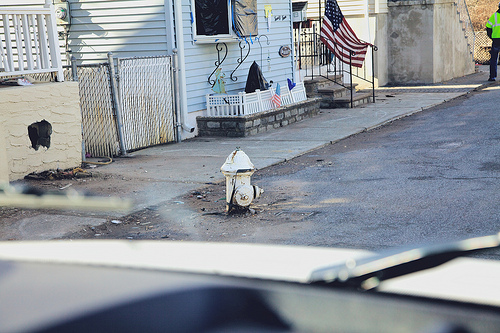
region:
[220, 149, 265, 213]
A white fire hydrant.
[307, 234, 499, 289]
A very close up windshield wiper.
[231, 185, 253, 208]
Large round white cap on a fire hydrant.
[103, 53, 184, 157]
A metal chain link gate.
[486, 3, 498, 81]
A person standing in dark jeans and a green vest.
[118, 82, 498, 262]
A grey concrete road.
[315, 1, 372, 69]
A red, white and blue larger American flag.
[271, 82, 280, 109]
A smaller red, white and blue American flag in front of a house.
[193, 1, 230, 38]
A black trashbag covering a window.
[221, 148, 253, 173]
The very top dome of a white hydrant.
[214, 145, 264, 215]
An old fire hydrant on a city street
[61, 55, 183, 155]
An old white gate between two buildings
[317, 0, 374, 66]
American flag hanging on a front porch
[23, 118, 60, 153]
Hole in a cement wall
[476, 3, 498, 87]
A construction worker on a city street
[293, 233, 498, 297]
A windshield wiper in a car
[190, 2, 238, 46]
Open window on an old house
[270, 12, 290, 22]
Metal address numbers on a house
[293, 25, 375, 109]
Metal porch railing by a front door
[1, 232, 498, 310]
The hood of a car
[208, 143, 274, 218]
Hydrant in the ground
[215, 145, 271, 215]
Hydrant is in the ground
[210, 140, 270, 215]
Fire hydrant in the ground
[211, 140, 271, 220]
Fire hydrant is in the ground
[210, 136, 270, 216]
White hydrant is in the ground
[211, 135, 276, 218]
White fire hydrant in the ground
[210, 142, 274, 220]
White fire hydrant is in the ground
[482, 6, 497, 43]
Man wearing a green reflective vest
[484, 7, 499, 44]
Man is wearing a green reflective vest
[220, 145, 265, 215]
short white fire hydrant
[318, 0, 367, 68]
American flag on porch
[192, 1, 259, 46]
black plastic taped around windows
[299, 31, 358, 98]
wrought iron railing on stairs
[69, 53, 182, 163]
white and grey chain link fence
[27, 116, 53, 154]
hole in concrete wall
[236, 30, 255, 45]
blue tape holding plastic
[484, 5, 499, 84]
man in green safety vest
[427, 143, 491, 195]
cracks in pavement on road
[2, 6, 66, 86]
white railing around porch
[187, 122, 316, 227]
a white fire hyrant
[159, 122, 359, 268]
a fire hydrant in the road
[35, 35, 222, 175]
a silver metal fence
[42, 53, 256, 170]
a metal fence along a building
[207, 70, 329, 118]
a white fence along a building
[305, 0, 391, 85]
the american flag on a building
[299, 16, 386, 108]
black railings on a staircase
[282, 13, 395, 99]
a staircase in front of a building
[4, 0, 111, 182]
a white railing on a building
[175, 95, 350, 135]
a stone wall along a building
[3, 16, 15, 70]
white wooden fence board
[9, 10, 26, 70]
white wooden fence board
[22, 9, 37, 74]
white wooden fence board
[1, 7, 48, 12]
white wooden fence board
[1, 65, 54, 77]
white wooden fence board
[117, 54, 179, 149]
the fence is old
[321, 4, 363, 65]
a flag is waving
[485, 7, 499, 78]
a person is standing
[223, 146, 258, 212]
the hydrant is white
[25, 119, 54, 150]
a hole in the wall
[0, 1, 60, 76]
the railing is white